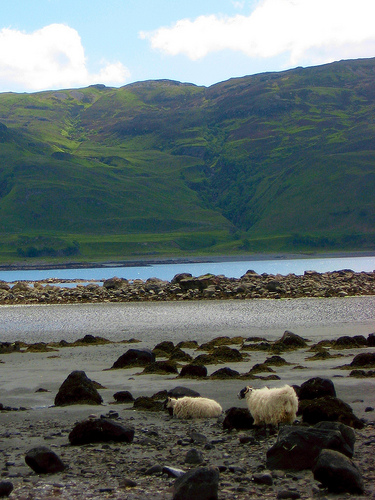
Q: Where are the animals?
A: Near large rocks.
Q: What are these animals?
A: Sheep.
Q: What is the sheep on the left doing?
A: Lying down.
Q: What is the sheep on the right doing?
A: Standing.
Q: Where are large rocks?
A: On the shoreline.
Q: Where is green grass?
A: On the hills.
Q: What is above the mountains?
A: Blue sky and white clouds.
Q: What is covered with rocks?
A: Shoreline.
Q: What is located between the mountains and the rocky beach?
A: Lake.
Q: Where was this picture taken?
A: The seaside.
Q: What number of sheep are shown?
A: Two.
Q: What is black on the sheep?
A: Faces.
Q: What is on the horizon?
A: Hills.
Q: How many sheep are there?
A: Two.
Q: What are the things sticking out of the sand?
A: Rocks.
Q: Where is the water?
A: Behind the rocks.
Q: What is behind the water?
A: A mountain.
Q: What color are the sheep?
A: White.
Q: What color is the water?
A: Blue.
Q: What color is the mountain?
A: Green.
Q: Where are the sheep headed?
A: Toward the water.